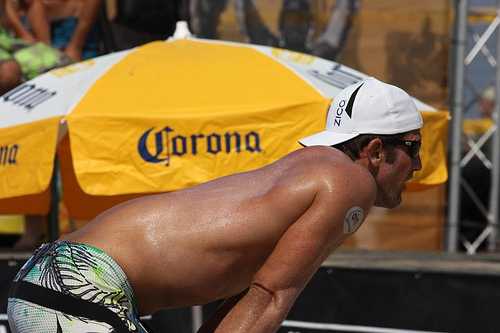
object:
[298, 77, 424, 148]
cap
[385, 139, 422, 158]
sunglasses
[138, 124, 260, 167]
word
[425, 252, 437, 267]
ground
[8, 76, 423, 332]
he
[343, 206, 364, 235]
sticker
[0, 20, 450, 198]
umbrella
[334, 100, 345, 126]
lettering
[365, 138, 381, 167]
ear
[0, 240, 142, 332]
shorts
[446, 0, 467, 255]
pole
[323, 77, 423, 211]
head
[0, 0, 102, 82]
people